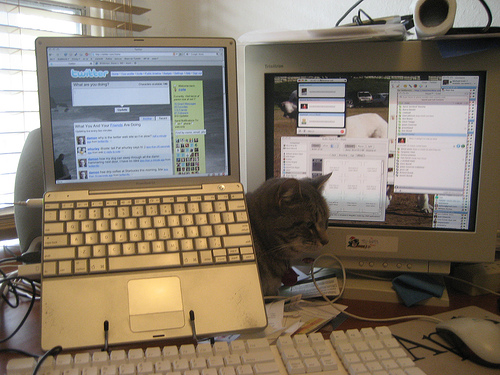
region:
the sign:
[30, 22, 291, 352]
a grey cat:
[212, 152, 364, 293]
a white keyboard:
[8, 317, 469, 372]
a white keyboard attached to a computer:
[8, 313, 405, 373]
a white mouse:
[327, 266, 498, 373]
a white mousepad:
[322, 277, 497, 372]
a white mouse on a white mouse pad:
[341, 271, 496, 365]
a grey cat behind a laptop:
[170, 148, 366, 329]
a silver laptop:
[18, 44, 288, 337]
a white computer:
[227, 38, 473, 284]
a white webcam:
[395, 2, 466, 48]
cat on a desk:
[262, 165, 359, 320]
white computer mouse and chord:
[295, 271, 495, 367]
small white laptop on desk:
[18, 98, 242, 368]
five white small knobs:
[331, 259, 433, 273]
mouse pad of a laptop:
[111, 269, 191, 354]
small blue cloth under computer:
[360, 269, 465, 339]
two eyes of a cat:
[285, 206, 348, 236]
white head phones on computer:
[349, 2, 484, 49]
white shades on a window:
[9, 3, 148, 213]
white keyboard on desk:
[25, 319, 400, 373]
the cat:
[174, 143, 304, 249]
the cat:
[228, 118, 450, 370]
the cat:
[242, 121, 362, 301]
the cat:
[206, 87, 308, 358]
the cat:
[271, 151, 328, 366]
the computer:
[51, 145, 267, 371]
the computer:
[39, 14, 241, 268]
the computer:
[26, 16, 321, 373]